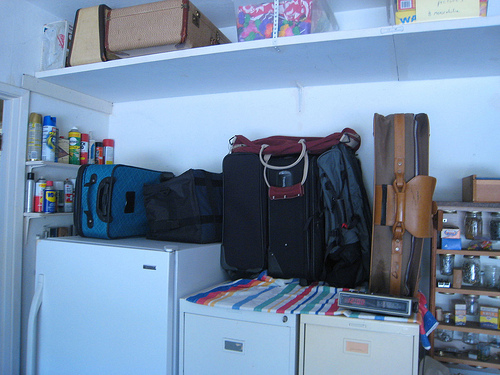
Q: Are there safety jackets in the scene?
A: No, there are no safety jackets.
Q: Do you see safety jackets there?
A: No, there are no safety jackets.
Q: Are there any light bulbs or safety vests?
A: No, there are no safety vests or light bulbs.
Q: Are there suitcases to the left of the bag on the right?
A: Yes, there are suitcases to the left of the bag.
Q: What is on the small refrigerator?
A: The suitcases are on the freezer.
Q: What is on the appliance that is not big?
A: The suitcases are on the freezer.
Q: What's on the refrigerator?
A: The suitcases are on the freezer.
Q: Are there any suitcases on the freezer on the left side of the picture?
A: Yes, there are suitcases on the freezer.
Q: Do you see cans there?
A: Yes, there is a can.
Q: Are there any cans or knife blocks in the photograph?
A: Yes, there is a can.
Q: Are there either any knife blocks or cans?
A: Yes, there is a can.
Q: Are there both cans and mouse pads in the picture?
A: No, there is a can but no mouse pads.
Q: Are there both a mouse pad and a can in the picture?
A: No, there is a can but no mouse pads.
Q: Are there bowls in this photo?
A: No, there are no bowls.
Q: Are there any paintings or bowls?
A: No, there are no bowls or paintings.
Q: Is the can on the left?
A: Yes, the can is on the left of the image.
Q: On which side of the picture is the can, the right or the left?
A: The can is on the left of the image.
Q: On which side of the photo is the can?
A: The can is on the left of the image.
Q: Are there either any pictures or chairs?
A: No, there are no chairs or pictures.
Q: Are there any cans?
A: Yes, there is a can.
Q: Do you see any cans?
A: Yes, there is a can.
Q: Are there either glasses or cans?
A: Yes, there is a can.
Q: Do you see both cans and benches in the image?
A: No, there is a can but no benches.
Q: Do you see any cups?
A: No, there are no cups.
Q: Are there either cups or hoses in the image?
A: No, there are no cups or hoses.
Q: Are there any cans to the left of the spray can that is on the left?
A: Yes, there is a can to the left of the spray can.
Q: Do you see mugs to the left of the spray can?
A: No, there is a can to the left of the spray can.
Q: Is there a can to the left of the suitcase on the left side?
A: Yes, there is a can to the left of the suitcase.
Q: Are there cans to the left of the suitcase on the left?
A: Yes, there is a can to the left of the suitcase.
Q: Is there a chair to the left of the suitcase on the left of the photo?
A: No, there is a can to the left of the suitcase.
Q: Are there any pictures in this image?
A: No, there are no pictures.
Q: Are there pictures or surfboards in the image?
A: No, there are no pictures or surfboards.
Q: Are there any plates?
A: No, there are no plates.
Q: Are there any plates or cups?
A: No, there are no plates or cups.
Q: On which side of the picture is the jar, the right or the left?
A: The jar is on the right of the image.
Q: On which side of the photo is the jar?
A: The jar is on the right of the image.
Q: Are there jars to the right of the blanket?
A: Yes, there is a jar to the right of the blanket.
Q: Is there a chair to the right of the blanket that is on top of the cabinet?
A: No, there is a jar to the right of the blanket.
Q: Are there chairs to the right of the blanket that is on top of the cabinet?
A: No, there is a jar to the right of the blanket.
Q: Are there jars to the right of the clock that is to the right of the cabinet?
A: Yes, there is a jar to the right of the clock.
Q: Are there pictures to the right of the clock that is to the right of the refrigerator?
A: No, there is a jar to the right of the clock.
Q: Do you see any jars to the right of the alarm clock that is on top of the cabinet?
A: Yes, there is a jar to the right of the alarm clock.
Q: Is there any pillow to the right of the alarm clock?
A: No, there is a jar to the right of the alarm clock.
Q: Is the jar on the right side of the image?
A: Yes, the jar is on the right of the image.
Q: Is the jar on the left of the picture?
A: No, the jar is on the right of the image.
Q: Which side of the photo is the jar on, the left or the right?
A: The jar is on the right of the image.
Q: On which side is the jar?
A: The jar is on the right of the image.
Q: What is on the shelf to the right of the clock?
A: The jar is on the shelf.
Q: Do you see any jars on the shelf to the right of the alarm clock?
A: Yes, there is a jar on the shelf.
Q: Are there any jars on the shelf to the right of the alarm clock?
A: Yes, there is a jar on the shelf.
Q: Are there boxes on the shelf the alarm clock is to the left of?
A: No, there is a jar on the shelf.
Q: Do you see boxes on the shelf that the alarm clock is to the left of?
A: No, there is a jar on the shelf.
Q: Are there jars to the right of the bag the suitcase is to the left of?
A: Yes, there is a jar to the right of the bag.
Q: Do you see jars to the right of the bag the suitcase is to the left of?
A: Yes, there is a jar to the right of the bag.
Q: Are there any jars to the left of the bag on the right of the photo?
A: No, the jar is to the right of the bag.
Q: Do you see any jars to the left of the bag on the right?
A: No, the jar is to the right of the bag.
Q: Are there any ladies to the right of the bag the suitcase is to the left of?
A: No, there is a jar to the right of the bag.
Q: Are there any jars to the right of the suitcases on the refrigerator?
A: Yes, there is a jar to the right of the suitcases.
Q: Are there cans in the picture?
A: Yes, there is a can.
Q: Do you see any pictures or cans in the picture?
A: Yes, there is a can.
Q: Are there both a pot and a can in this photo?
A: No, there is a can but no pots.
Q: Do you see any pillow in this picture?
A: No, there are no pillows.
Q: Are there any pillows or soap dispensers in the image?
A: No, there are no pillows or soap dispensers.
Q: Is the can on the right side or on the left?
A: The can is on the left of the image.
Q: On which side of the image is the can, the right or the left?
A: The can is on the left of the image.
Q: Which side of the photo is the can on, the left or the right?
A: The can is on the left of the image.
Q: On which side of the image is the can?
A: The can is on the left of the image.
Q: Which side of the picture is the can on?
A: The can is on the left of the image.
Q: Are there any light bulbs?
A: No, there are no light bulbs.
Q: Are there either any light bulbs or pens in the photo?
A: No, there are no light bulbs or pens.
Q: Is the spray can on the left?
A: Yes, the spray can is on the left of the image.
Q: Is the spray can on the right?
A: No, the spray can is on the left of the image.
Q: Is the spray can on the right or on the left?
A: The spray can is on the left of the image.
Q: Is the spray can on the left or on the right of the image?
A: The spray can is on the left of the image.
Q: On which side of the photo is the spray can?
A: The spray can is on the left of the image.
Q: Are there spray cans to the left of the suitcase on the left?
A: Yes, there is a spray can to the left of the suitcase.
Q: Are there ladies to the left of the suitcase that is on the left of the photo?
A: No, there is a spray can to the left of the suitcase.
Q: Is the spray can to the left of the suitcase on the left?
A: Yes, the spray can is to the left of the suitcase.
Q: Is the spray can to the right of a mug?
A: No, the spray can is to the right of the can.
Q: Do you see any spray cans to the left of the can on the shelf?
A: Yes, there is a spray can to the left of the can.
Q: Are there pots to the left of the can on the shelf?
A: No, there is a spray can to the left of the can.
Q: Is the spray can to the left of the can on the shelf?
A: Yes, the spray can is to the left of the can.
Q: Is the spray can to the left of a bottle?
A: No, the spray can is to the left of the can.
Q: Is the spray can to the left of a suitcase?
A: Yes, the spray can is to the left of a suitcase.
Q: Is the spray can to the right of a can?
A: Yes, the spray can is to the right of a can.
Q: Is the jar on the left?
A: No, the jar is on the right of the image.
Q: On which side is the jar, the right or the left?
A: The jar is on the right of the image.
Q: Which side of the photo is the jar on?
A: The jar is on the right of the image.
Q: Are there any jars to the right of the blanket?
A: Yes, there is a jar to the right of the blanket.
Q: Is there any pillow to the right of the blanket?
A: No, there is a jar to the right of the blanket.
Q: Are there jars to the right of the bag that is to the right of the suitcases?
A: Yes, there is a jar to the right of the bag.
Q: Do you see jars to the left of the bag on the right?
A: No, the jar is to the right of the bag.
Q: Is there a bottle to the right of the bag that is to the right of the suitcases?
A: No, there is a jar to the right of the bag.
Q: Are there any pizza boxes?
A: No, there are no pizza boxes.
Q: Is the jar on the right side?
A: Yes, the jar is on the right of the image.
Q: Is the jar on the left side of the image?
A: No, the jar is on the right of the image.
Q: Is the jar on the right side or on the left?
A: The jar is on the right of the image.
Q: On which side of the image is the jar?
A: The jar is on the right of the image.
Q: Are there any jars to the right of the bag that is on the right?
A: Yes, there is a jar to the right of the bag.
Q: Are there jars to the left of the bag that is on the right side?
A: No, the jar is to the right of the bag.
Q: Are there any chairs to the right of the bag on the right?
A: No, there is a jar to the right of the bag.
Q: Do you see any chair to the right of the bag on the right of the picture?
A: No, there is a jar to the right of the bag.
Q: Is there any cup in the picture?
A: No, there are no cups.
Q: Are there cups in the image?
A: No, there are no cups.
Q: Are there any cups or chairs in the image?
A: No, there are no cups or chairs.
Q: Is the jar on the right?
A: Yes, the jar is on the right of the image.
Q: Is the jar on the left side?
A: No, the jar is on the right of the image.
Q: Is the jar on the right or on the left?
A: The jar is on the right of the image.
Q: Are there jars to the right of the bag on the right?
A: Yes, there is a jar to the right of the bag.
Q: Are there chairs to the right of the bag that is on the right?
A: No, there is a jar to the right of the bag.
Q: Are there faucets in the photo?
A: No, there are no faucets.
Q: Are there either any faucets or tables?
A: No, there are no faucets or tables.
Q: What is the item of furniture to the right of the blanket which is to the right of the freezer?
A: The piece of furniture is a shelf.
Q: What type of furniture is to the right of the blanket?
A: The piece of furniture is a shelf.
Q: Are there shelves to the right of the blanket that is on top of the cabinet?
A: Yes, there is a shelf to the right of the blanket.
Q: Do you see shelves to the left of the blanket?
A: No, the shelf is to the right of the blanket.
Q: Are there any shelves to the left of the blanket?
A: No, the shelf is to the right of the blanket.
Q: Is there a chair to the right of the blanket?
A: No, there is a shelf to the right of the blanket.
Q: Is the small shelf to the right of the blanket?
A: Yes, the shelf is to the right of the blanket.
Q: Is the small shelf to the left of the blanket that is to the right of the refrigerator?
A: No, the shelf is to the right of the blanket.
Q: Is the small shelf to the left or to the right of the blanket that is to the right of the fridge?
A: The shelf is to the right of the blanket.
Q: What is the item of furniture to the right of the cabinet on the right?
A: The piece of furniture is a shelf.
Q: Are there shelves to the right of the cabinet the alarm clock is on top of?
A: Yes, there is a shelf to the right of the cabinet.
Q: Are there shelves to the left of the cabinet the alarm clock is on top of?
A: No, the shelf is to the right of the cabinet.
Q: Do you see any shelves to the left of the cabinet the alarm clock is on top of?
A: No, the shelf is to the right of the cabinet.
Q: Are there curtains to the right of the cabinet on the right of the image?
A: No, there is a shelf to the right of the cabinet.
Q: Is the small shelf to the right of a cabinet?
A: Yes, the shelf is to the right of a cabinet.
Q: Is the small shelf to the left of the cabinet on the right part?
A: No, the shelf is to the right of the cabinet.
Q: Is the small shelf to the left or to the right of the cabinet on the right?
A: The shelf is to the right of the cabinet.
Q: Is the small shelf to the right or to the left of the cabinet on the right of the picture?
A: The shelf is to the right of the cabinet.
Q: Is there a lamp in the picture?
A: No, there are no lamps.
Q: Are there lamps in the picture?
A: No, there are no lamps.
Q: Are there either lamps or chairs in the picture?
A: No, there are no lamps or chairs.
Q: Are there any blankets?
A: Yes, there is a blanket.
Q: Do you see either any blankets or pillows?
A: Yes, there is a blanket.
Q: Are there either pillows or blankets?
A: Yes, there is a blanket.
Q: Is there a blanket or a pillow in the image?
A: Yes, there is a blanket.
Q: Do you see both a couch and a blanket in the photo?
A: No, there is a blanket but no couches.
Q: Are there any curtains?
A: No, there are no curtains.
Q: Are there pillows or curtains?
A: No, there are no curtains or pillows.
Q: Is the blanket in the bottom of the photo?
A: Yes, the blanket is in the bottom of the image.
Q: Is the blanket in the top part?
A: No, the blanket is in the bottom of the image.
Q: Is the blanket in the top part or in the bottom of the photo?
A: The blanket is in the bottom of the image.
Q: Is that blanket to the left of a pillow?
A: No, the blanket is to the left of a jar.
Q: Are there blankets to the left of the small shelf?
A: Yes, there is a blanket to the left of the shelf.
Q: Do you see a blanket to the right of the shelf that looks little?
A: No, the blanket is to the left of the shelf.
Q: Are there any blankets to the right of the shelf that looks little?
A: No, the blanket is to the left of the shelf.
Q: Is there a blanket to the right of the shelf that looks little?
A: No, the blanket is to the left of the shelf.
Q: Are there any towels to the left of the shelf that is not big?
A: No, there is a blanket to the left of the shelf.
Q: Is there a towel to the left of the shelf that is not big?
A: No, there is a blanket to the left of the shelf.